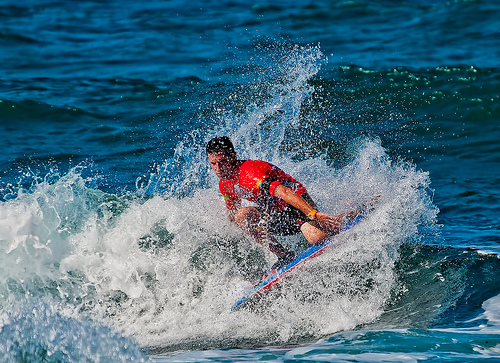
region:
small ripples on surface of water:
[29, 8, 159, 73]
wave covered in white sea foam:
[4, 191, 67, 287]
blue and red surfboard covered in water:
[218, 214, 419, 319]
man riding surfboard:
[143, 110, 410, 327]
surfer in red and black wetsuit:
[178, 140, 332, 260]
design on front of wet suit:
[227, 180, 263, 202]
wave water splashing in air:
[219, 31, 349, 133]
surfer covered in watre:
[130, 88, 437, 329]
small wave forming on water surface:
[410, 237, 497, 336]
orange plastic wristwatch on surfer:
[300, 203, 323, 223]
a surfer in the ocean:
[77, 45, 450, 360]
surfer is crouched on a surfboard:
[180, 122, 400, 313]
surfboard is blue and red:
[221, 205, 386, 310]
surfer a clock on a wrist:
[301, 203, 325, 228]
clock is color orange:
[300, 201, 325, 226]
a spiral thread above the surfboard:
[247, 198, 284, 297]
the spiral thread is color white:
[253, 200, 279, 279]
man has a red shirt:
[189, 123, 316, 239]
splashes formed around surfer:
[80, 29, 445, 337]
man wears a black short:
[186, 118, 360, 273]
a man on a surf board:
[193, 131, 406, 302]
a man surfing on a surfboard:
[187, 125, 385, 330]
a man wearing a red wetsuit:
[181, 132, 372, 314]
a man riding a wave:
[167, 114, 384, 344]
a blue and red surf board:
[234, 200, 379, 310]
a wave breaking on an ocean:
[2, 120, 194, 357]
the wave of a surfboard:
[309, 83, 471, 333]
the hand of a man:
[313, 207, 352, 240]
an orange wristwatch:
[304, 203, 319, 223]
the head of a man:
[196, 135, 236, 179]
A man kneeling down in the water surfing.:
[204, 138, 344, 263]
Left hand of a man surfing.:
[316, 213, 345, 233]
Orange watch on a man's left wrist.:
[306, 204, 318, 221]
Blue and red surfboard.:
[232, 198, 380, 313]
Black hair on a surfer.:
[206, 135, 238, 157]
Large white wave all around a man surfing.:
[7, 77, 419, 346]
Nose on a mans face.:
[216, 163, 224, 174]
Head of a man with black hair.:
[206, 138, 236, 178]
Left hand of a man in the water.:
[316, 213, 345, 234]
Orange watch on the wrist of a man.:
[303, 210, 319, 220]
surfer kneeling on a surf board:
[207, 117, 401, 336]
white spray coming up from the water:
[207, 42, 356, 139]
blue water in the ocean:
[71, 20, 151, 99]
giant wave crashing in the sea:
[39, 140, 199, 309]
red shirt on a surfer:
[201, 143, 318, 260]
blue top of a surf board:
[240, 239, 322, 289]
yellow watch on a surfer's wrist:
[301, 203, 321, 224]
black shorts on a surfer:
[241, 198, 321, 242]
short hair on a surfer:
[207, 134, 232, 154]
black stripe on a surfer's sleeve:
[250, 173, 277, 196]